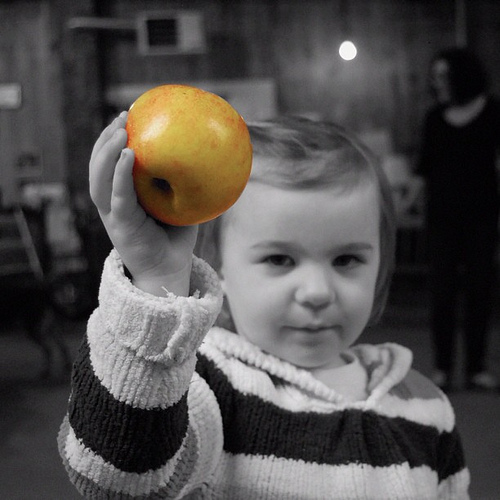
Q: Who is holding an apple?
A: A child.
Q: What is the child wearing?
A: A sweater.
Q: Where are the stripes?
A: On the sweater.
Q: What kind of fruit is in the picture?
A: An apple.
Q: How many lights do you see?
A: One.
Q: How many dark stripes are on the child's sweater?
A: Two.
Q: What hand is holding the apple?
A: Right hand.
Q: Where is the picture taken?
A: In a house.